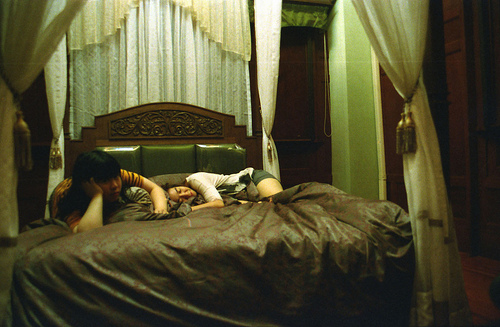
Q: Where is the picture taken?
A: A bedroom.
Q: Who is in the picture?
A: Two women.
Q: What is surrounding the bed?
A: Curtains.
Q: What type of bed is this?
A: Four poster.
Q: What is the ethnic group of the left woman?
A: Asian.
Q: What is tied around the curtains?
A: Tassels.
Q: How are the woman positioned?
A: Laying down.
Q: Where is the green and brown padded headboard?
A: At the top of the bed behind the girls.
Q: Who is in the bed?
A: Two young women.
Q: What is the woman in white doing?
A: Sleeping.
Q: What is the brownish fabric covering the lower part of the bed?
A: A comforter.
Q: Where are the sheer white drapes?
A: On the bedposts and behind the headboard.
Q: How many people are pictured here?
A: Two.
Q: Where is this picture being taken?
A: A bedrrom.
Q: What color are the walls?
A: Green.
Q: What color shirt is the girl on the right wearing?
A: White.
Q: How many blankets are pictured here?
A: One.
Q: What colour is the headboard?
A: Brown and Green.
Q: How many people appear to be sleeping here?
A: One.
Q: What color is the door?
A: Brown.